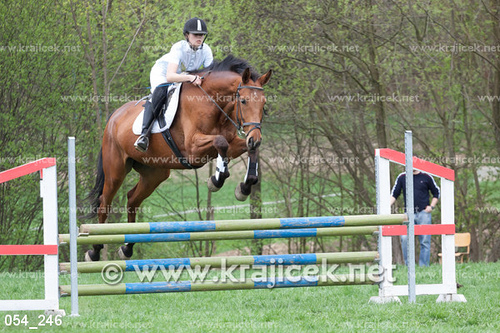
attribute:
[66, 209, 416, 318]
hurdle — green, blue, striped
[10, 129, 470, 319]
fencing — red, white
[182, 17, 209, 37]
helmet — black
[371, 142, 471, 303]
gate — red, white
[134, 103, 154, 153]
boots — tall, black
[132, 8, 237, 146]
female — light, colored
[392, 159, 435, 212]
shirt — blue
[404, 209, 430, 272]
jeans — blue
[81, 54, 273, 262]
horse — brown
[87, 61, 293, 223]
horse — brown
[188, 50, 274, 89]
mane — black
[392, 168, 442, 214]
top — blue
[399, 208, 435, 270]
jeans — blue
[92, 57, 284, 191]
hair — black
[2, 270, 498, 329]
grass — green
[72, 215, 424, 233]
pole — blue, yellow, jumping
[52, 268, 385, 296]
pole — blue, yellow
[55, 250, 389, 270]
pole — blue, yellow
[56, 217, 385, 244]
pole — blue, yellow